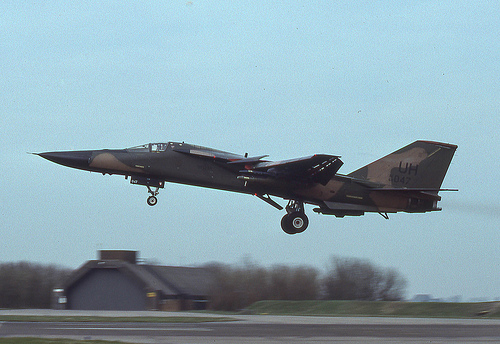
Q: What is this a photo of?
A: A jet.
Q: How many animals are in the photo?
A: None.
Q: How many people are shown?
A: None.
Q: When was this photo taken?
A: Daytime.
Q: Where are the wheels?
A: On the bottom of the jet.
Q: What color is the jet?
A: Camouflage.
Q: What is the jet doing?
A: Landing.